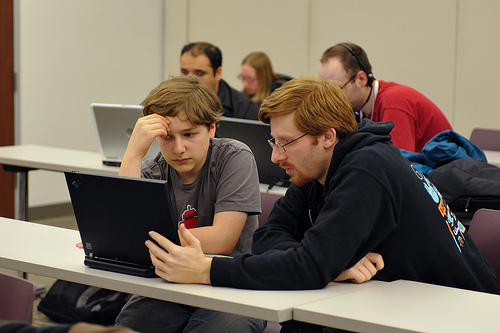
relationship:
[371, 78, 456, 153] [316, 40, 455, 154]
sweater worn by man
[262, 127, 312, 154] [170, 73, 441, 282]
eyeglasses worn by man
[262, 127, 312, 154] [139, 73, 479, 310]
eyeglasses worn by guy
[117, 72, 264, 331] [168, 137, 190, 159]
person has nose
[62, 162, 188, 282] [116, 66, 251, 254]
computer used by guy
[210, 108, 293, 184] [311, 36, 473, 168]
computer used by guy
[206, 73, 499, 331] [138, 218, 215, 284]
people has hand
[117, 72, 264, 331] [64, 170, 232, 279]
person looking at computer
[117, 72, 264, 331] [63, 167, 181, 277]
person looking at computer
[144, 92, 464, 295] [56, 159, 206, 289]
person looking at computer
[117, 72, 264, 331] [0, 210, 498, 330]
person sitting at table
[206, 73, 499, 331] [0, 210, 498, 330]
people sitting at table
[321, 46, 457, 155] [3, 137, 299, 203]
person sitting at table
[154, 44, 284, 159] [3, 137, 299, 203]
person sitting at table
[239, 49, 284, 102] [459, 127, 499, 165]
person sitting at table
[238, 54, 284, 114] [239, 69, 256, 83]
girl is wearing glasses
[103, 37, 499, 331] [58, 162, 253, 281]
people looking at laptop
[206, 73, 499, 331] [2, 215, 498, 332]
people sitting at tables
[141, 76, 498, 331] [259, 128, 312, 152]
man wearing glasses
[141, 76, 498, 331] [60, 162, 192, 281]
man touching laptop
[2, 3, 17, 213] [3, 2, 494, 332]
door into room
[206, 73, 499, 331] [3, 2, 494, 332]
people sitting in a room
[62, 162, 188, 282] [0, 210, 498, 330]
computer on table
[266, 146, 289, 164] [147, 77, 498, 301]
nose of guy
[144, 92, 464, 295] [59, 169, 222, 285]
person looking at a computer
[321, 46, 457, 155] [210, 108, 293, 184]
person looking at a computer